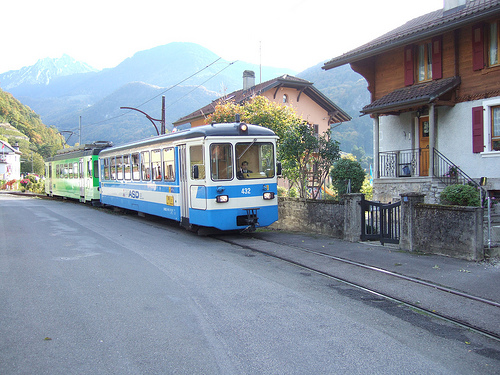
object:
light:
[240, 124, 246, 131]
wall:
[268, 197, 358, 239]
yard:
[268, 134, 374, 224]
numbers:
[241, 187, 251, 195]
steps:
[432, 150, 500, 261]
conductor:
[237, 161, 254, 179]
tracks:
[226, 233, 498, 344]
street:
[0, 190, 499, 373]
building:
[320, 0, 498, 265]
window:
[412, 36, 436, 84]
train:
[98, 121, 281, 232]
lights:
[219, 193, 231, 202]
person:
[237, 160, 253, 179]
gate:
[344, 192, 420, 252]